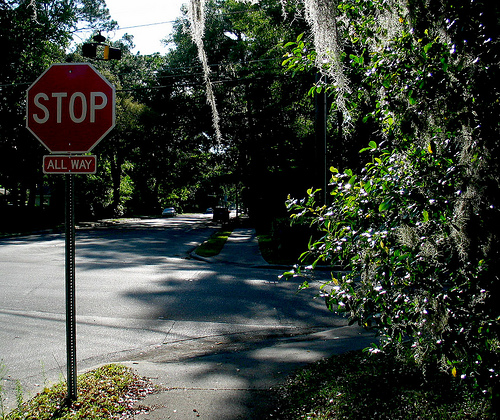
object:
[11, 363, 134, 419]
grass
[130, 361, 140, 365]
curb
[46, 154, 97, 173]
lettering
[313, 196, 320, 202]
leaves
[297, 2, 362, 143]
moss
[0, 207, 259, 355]
road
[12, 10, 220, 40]
wire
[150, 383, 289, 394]
seam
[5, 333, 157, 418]
corner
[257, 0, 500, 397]
tree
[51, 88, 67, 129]
letter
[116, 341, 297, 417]
sidewalk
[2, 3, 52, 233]
trees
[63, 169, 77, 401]
pole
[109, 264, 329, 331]
shadows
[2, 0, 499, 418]
area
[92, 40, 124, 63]
stoplight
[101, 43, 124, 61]
light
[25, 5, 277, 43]
line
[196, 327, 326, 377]
area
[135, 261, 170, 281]
sunlight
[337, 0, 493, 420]
bush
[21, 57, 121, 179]
sign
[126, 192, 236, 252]
block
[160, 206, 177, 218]
car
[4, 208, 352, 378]
street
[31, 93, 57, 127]
letter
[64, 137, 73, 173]
screws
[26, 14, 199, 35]
light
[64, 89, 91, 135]
letter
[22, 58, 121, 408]
sign